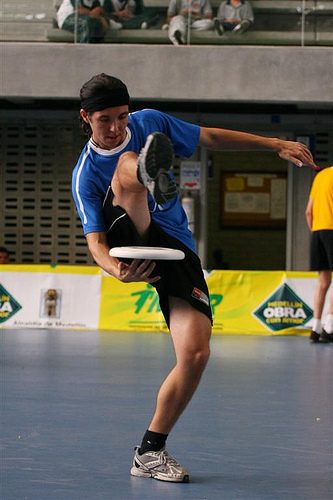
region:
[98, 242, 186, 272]
Man holding a frisbee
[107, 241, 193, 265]
Man is holding a frisbee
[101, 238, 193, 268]
Man holding a white frisbee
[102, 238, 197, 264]
Man is holding a white frisbee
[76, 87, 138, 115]
Man wearing a headband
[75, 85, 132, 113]
Man is wearing a headband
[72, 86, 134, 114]
Man wearing a black headband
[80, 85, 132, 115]
Man is wearing a black headband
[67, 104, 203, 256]
Man wearing a blue and white shirt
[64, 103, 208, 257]
Man is wearing a blue and white shirt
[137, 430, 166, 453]
a man's black sock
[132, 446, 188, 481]
a white and grey shoe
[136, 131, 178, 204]
a white and grey shoe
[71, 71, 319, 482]
a man playing with frisbee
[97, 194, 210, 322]
a man's short black pants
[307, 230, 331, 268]
a man's short black pants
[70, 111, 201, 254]
a blue and white jersey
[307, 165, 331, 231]
a bright yellow t-shirt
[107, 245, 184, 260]
a round white frisbee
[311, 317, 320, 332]
a man's white sock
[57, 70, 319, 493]
man playing with a frisbee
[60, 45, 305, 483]
man playing with a white frisbee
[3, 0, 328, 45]
spectators watching from above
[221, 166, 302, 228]
bulletin board with papers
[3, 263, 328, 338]
fencing with sponsor's name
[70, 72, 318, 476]
putting the frisbee underneath his leg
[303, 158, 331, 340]
man wearing yellow shirt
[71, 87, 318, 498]
player with a blue shirt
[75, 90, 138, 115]
black headband around his head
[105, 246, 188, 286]
balancing the frisbee on his fingertips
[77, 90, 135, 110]
a black headband on a person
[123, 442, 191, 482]
a white and black tennis shoe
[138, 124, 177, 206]
a white and black tennis shoe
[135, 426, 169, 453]
a black long sock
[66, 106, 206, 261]
a blue and white shirt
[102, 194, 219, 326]
black and white athletic pants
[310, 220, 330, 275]
black althletic shorts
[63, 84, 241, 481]
a man balancing a frisbee under his leg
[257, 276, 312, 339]
a logo that says obra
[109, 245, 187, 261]
White frisbee on man's fingers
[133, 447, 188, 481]
Gray and white shoe on man's foot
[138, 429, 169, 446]
Black sock on man's foot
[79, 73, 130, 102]
Black hat on man's head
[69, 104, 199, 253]
Blue shirt with white stripe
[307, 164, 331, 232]
Yellow shirt on man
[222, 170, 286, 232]
Bulletin board on back wall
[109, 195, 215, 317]
Black shorts on man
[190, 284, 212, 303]
Tag on black shorts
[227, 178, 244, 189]
Yellow paper on bulletin board